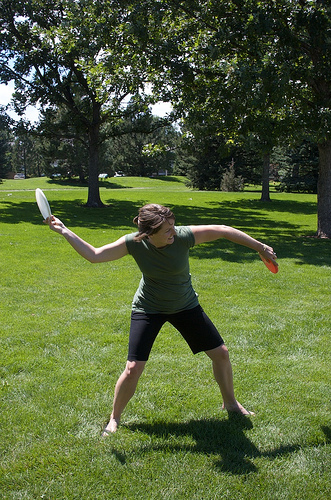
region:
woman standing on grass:
[25, 178, 293, 436]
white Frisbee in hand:
[28, 181, 61, 234]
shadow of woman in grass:
[117, 414, 265, 478]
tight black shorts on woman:
[118, 299, 229, 371]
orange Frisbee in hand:
[254, 240, 287, 278]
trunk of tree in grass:
[77, 131, 115, 211]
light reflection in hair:
[140, 201, 166, 226]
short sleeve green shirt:
[121, 226, 207, 320]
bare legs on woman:
[107, 344, 241, 417]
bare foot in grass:
[221, 399, 265, 422]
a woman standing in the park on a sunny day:
[50, 213, 274, 436]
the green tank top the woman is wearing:
[124, 228, 201, 306]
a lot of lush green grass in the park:
[6, 187, 307, 494]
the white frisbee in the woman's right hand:
[30, 186, 51, 218]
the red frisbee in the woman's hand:
[257, 255, 276, 272]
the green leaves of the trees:
[1, 5, 328, 152]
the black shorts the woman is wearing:
[123, 307, 218, 358]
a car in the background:
[9, 168, 19, 177]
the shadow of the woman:
[118, 413, 298, 471]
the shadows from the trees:
[220, 195, 312, 273]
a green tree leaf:
[222, 137, 233, 146]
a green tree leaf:
[92, 136, 96, 140]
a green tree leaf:
[207, 90, 218, 107]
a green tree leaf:
[280, 89, 285, 92]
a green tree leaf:
[39, 29, 46, 36]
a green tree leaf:
[84, 71, 89, 75]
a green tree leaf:
[93, 65, 101, 71]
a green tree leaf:
[145, 142, 153, 147]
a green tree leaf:
[226, 137, 232, 143]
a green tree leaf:
[183, 132, 187, 136]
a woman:
[29, 185, 279, 436]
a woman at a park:
[25, 182, 329, 456]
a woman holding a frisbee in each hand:
[26, 186, 294, 440]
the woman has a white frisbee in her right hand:
[24, 165, 284, 451]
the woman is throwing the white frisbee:
[29, 177, 295, 438]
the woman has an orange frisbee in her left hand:
[34, 188, 286, 439]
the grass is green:
[16, 197, 314, 499]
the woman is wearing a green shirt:
[27, 185, 282, 438]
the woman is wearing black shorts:
[33, 179, 272, 436]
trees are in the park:
[22, 54, 330, 237]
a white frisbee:
[19, 182, 80, 245]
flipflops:
[82, 382, 283, 443]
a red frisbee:
[228, 225, 303, 303]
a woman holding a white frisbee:
[17, 165, 300, 329]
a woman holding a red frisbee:
[20, 166, 279, 308]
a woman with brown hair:
[19, 147, 275, 371]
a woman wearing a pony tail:
[54, 189, 248, 335]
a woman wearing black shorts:
[108, 211, 265, 367]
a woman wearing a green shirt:
[97, 209, 265, 374]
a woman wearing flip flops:
[81, 88, 295, 448]